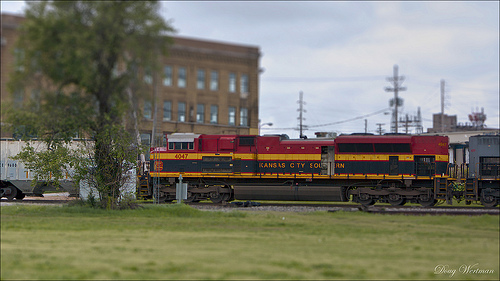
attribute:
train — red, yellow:
[1, 130, 499, 222]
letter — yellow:
[258, 159, 263, 173]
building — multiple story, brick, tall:
[0, 7, 274, 150]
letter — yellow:
[278, 161, 287, 168]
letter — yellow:
[262, 162, 269, 169]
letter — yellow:
[264, 162, 272, 170]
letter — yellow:
[153, 144, 330, 192]